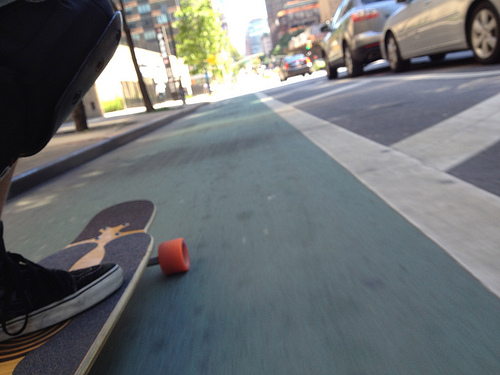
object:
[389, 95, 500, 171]
line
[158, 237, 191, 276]
wheel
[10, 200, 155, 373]
black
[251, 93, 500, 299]
lines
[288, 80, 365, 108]
line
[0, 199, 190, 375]
skateboard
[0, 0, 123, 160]
pads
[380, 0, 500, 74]
vehicular traffic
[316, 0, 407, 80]
vehicular traffic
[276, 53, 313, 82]
vehicular traffic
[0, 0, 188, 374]
vehicular traffic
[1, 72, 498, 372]
street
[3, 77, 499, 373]
road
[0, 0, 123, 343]
person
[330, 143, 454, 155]
white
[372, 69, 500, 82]
line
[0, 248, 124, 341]
shoe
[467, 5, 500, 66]
wheels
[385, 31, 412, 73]
wheels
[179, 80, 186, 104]
bike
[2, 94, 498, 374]
bike path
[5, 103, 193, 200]
curb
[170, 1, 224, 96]
tree